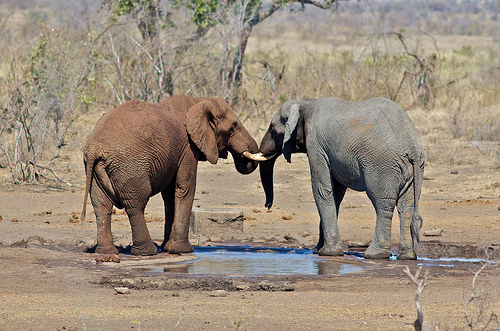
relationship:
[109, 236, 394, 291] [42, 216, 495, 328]
puddle on ground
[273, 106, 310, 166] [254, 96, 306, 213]
ear on head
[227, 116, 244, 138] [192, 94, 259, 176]
eye on head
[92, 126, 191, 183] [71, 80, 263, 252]
lines on skin